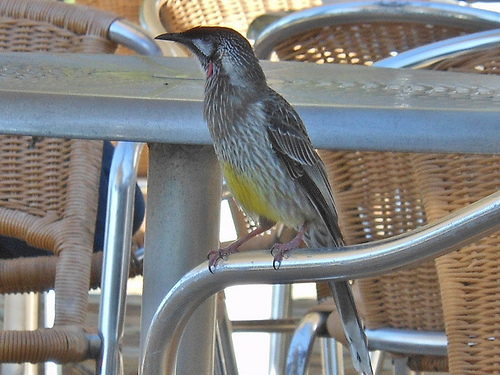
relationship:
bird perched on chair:
[147, 23, 376, 373] [137, 192, 499, 372]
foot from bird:
[266, 237, 294, 268] [147, 23, 376, 373]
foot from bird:
[201, 243, 244, 276] [147, 23, 376, 373]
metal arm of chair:
[135, 181, 495, 373] [137, 192, 499, 372]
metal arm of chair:
[112, 25, 160, 221] [1, 2, 133, 374]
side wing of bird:
[263, 92, 355, 251] [147, 23, 376, 373]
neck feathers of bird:
[203, 63, 274, 137] [147, 23, 376, 373]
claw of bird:
[208, 240, 237, 275] [147, 23, 376, 373]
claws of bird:
[273, 258, 277, 271] [147, 23, 376, 373]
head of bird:
[148, 21, 274, 97] [147, 23, 376, 373]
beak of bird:
[155, 29, 196, 50] [147, 23, 376, 373]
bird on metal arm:
[147, 23, 376, 373] [135, 181, 495, 373]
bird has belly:
[147, 23, 376, 373] [213, 157, 292, 225]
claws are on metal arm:
[189, 219, 312, 269] [135, 181, 495, 373]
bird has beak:
[147, 23, 376, 373] [155, 29, 196, 50]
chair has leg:
[1, 2, 133, 374] [92, 174, 142, 374]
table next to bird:
[6, 51, 500, 154] [147, 23, 376, 373]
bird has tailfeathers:
[147, 23, 376, 373] [312, 244, 383, 371]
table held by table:
[6, 51, 500, 154] [0, 48, 500, 154]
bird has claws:
[147, 23, 376, 373] [189, 219, 312, 269]